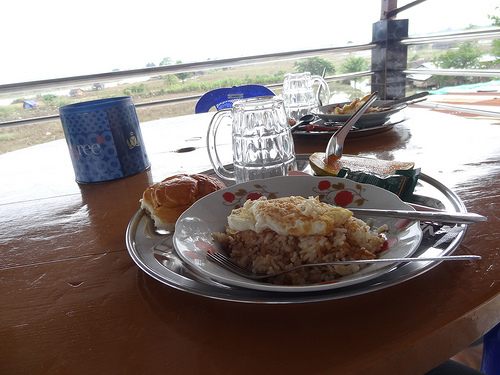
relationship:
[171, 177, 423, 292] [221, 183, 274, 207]
plate has roses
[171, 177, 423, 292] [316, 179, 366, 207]
plate has roses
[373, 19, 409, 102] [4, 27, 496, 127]
post for guardrail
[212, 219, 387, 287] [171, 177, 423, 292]
rice on top of plate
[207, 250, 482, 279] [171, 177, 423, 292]
fork inside plate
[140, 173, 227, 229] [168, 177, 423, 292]
roll on top of plate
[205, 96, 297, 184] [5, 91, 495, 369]
cup on top of table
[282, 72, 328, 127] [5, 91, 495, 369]
cup on top of table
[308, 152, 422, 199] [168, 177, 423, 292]
fruit on top of plate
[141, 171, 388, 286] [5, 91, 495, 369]
food on top of table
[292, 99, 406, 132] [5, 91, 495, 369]
food on top of table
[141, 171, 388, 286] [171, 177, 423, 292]
food on top of plate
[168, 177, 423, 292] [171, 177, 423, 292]
plate beneath smaller plate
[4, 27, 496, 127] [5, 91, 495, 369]
guardrail behind table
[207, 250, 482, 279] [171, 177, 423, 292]
fork on top of plate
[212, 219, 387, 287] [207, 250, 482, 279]
rice near fork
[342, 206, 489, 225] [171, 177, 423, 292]
knife on top of plate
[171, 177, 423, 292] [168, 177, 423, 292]
plate sitting on top of plate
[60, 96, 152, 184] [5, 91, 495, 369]
container in sitting on top of table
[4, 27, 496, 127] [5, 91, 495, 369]
guardrail near table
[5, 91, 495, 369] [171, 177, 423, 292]
table underneath plate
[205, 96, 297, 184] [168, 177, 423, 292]
cup on top of plate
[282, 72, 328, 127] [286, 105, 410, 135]
cup on top of plate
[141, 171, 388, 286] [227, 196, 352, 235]
food has topping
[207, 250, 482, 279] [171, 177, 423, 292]
fork laying on top of plate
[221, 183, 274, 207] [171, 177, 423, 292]
roses are on plate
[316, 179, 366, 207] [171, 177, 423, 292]
roses are on plate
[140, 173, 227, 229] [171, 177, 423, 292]
roll on side of plate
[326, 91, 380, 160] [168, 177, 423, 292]
spoon on top of plate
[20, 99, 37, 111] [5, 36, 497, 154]
tent on top of ground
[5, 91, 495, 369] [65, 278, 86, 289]
table has nick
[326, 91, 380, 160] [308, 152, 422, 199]
spoon for fruit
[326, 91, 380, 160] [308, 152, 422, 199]
spoon scooping fruit